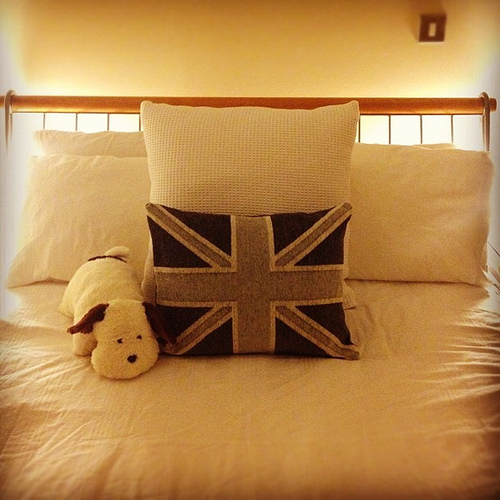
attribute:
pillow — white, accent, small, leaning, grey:
[108, 64, 395, 360]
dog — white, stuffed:
[45, 217, 174, 386]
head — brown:
[72, 280, 181, 371]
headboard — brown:
[17, 61, 488, 213]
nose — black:
[130, 347, 149, 361]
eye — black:
[90, 316, 153, 356]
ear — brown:
[78, 293, 118, 343]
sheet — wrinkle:
[422, 312, 491, 428]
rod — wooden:
[469, 88, 495, 175]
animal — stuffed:
[89, 242, 165, 367]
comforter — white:
[25, 99, 480, 299]